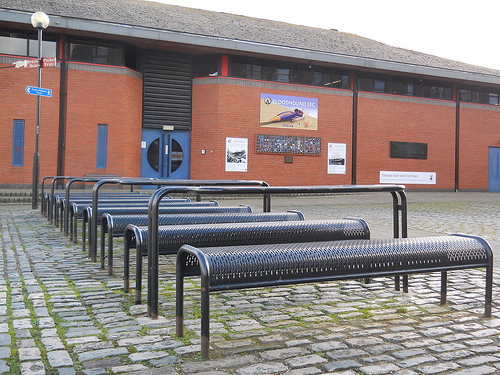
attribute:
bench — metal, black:
[183, 248, 496, 336]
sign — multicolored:
[241, 84, 335, 138]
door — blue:
[136, 122, 193, 199]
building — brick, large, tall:
[54, 5, 469, 179]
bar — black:
[134, 173, 417, 219]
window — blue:
[89, 115, 120, 171]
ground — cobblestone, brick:
[13, 233, 163, 375]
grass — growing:
[41, 293, 63, 325]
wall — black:
[147, 61, 190, 127]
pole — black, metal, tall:
[24, 23, 54, 208]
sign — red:
[19, 52, 73, 75]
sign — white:
[326, 136, 345, 178]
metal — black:
[114, 184, 405, 292]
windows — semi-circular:
[152, 127, 186, 174]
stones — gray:
[274, 320, 443, 371]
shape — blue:
[484, 140, 499, 191]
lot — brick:
[41, 170, 480, 344]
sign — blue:
[19, 84, 81, 104]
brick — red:
[216, 89, 252, 127]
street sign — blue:
[20, 80, 69, 108]